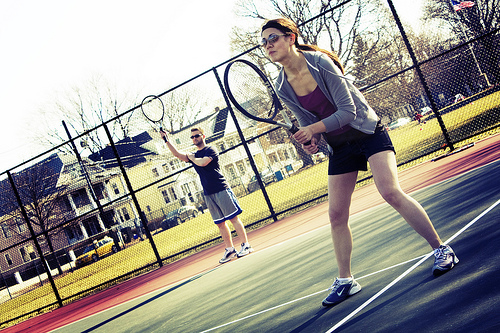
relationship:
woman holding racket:
[220, 13, 465, 305] [217, 53, 313, 158]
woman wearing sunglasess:
[220, 13, 465, 305] [254, 31, 285, 47]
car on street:
[76, 237, 122, 260] [29, 258, 88, 283]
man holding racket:
[175, 127, 252, 259] [138, 94, 174, 145]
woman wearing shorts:
[220, 13, 465, 305] [308, 133, 392, 172]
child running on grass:
[406, 108, 433, 127] [400, 119, 425, 143]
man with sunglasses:
[175, 127, 252, 259] [188, 132, 204, 143]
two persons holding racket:
[153, 18, 461, 310] [217, 53, 313, 158]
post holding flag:
[457, 15, 490, 90] [440, 1, 478, 17]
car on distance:
[76, 237, 122, 260] [51, 170, 107, 189]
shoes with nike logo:
[320, 272, 367, 310] [332, 285, 351, 299]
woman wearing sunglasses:
[220, 13, 465, 305] [259, 33, 286, 49]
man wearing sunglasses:
[175, 127, 252, 259] [188, 132, 204, 143]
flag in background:
[440, 1, 478, 17] [401, 2, 449, 46]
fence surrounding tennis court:
[44, 84, 255, 288] [68, 178, 499, 323]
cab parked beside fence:
[76, 237, 122, 260] [44, 84, 255, 288]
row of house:
[28, 159, 176, 228] [1, 72, 299, 241]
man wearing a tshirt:
[175, 127, 252, 259] [187, 148, 232, 193]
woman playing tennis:
[220, 13, 465, 305] [222, 56, 316, 287]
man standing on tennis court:
[175, 127, 252, 259] [68, 178, 499, 323]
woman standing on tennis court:
[220, 13, 465, 305] [68, 178, 499, 323]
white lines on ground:
[368, 243, 429, 281] [91, 290, 257, 329]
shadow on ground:
[443, 166, 499, 219] [91, 290, 257, 329]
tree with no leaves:
[284, 2, 371, 39] [343, 46, 372, 65]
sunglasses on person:
[188, 132, 204, 143] [175, 127, 252, 259]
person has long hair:
[220, 13, 465, 305] [265, 15, 345, 69]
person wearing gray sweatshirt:
[220, 13, 465, 305] [261, 52, 385, 145]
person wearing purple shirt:
[175, 127, 252, 259] [187, 148, 232, 193]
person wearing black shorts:
[220, 13, 465, 305] [308, 133, 392, 172]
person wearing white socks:
[220, 13, 465, 305] [336, 272, 358, 285]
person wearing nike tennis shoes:
[220, 13, 465, 305] [318, 242, 463, 310]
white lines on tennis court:
[368, 243, 429, 281] [68, 178, 499, 323]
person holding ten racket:
[175, 127, 252, 259] [138, 94, 174, 145]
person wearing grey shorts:
[175, 127, 252, 259] [197, 189, 248, 224]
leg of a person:
[369, 132, 455, 251] [220, 13, 465, 305]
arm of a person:
[292, 56, 358, 149] [220, 13, 465, 305]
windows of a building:
[13, 214, 41, 261] [0, 142, 129, 272]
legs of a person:
[296, 136, 459, 309] [220, 13, 465, 305]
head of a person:
[250, 11, 316, 68] [220, 13, 465, 305]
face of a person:
[257, 27, 289, 63] [220, 13, 465, 305]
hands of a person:
[289, 120, 317, 158] [220, 13, 465, 305]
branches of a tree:
[298, 3, 342, 37] [284, 2, 371, 39]